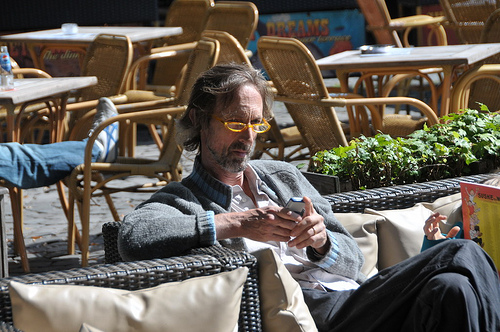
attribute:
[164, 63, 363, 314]
man — one, seated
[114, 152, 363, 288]
sweater — gray, grey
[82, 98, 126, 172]
sneaker — white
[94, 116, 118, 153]
stripes — blue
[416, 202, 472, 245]
hand — small, child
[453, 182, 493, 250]
book — children's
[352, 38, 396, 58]
ashtray — silver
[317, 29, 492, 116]
table — one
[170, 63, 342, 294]
man — one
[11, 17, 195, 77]
table — one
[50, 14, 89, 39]
holder — candle, small, glass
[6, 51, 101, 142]
table — one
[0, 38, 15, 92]
bottle — empty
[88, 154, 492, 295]
sofa — grey, patio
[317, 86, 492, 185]
bush — leafy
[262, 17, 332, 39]
word — orange, yellow, one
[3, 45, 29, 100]
bottle — empty, soda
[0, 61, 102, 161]
table — one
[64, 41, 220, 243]
chair — brown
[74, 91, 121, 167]
foot — human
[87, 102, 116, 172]
foot — human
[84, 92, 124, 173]
sneaker — white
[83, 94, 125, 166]
sneaker — one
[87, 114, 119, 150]
designs — blue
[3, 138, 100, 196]
leg — human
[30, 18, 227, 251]
chair — brown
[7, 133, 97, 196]
jeans — blue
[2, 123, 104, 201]
leg — human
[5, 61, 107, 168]
table — grey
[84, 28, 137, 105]
backrest — one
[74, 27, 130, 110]
chair — brown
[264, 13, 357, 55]
writing — orange, yellow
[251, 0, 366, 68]
poster — one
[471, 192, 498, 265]
paper — yellow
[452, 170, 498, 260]
book — one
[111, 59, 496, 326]
man — in gray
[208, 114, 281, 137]
glasses — amber-colored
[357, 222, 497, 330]
legs — crossed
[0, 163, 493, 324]
furniture — gray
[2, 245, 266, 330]
chair — gray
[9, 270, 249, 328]
pillow — beige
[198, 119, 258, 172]
beard — grey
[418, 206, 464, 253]
child's hand — outstreched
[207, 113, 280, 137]
man's glasses — yellow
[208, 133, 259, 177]
beard — grey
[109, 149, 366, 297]
sweater — grey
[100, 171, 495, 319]
couch — grey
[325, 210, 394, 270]
pillow — beige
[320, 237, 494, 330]
pants — blue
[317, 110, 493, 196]
plants — green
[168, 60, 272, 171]
hair — grey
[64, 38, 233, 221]
chair — brown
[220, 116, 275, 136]
glasses — yellow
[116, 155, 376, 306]
sweater — grey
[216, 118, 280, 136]
sunglasses — hipster-style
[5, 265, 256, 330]
pillow — beige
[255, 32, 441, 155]
chair — brown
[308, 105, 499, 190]
plants — green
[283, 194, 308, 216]
device — smart